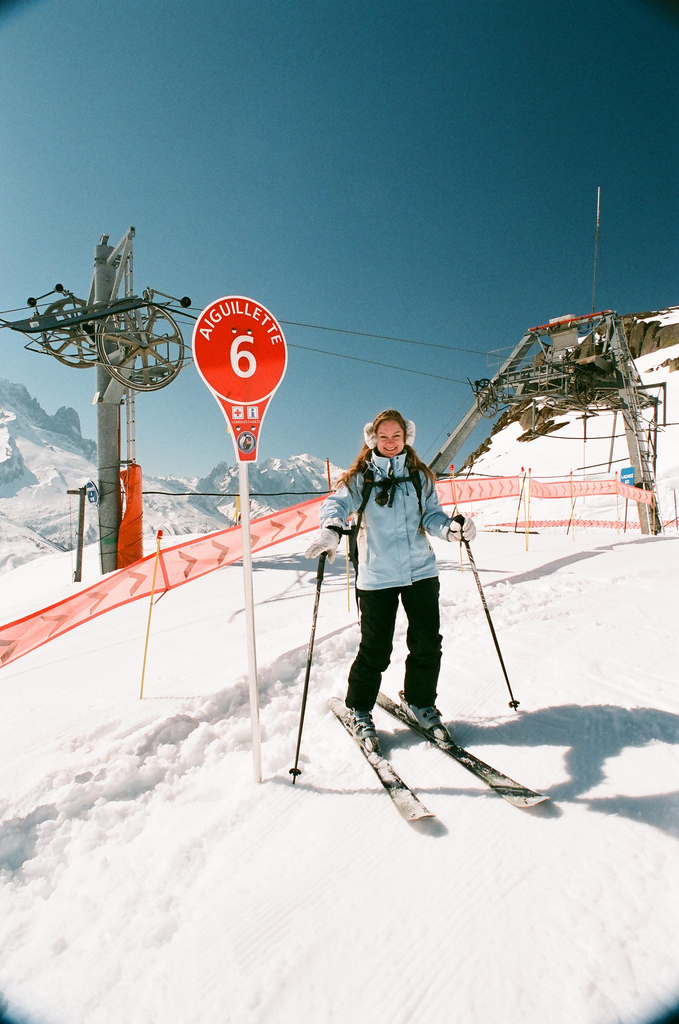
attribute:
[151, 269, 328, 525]
sign — red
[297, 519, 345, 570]
glove — white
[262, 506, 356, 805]
pole — black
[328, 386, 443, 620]
girl — smiling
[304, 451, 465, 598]
coat — blue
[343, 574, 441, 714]
pants — black